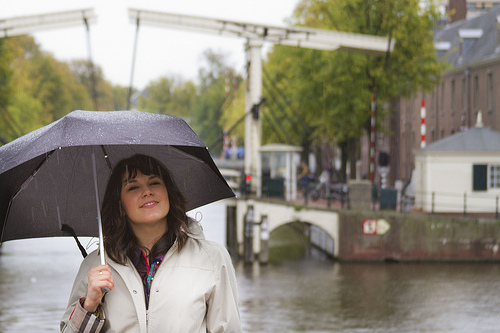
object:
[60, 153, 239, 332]
woman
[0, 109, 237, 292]
umbrella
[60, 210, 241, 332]
jacket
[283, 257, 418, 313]
water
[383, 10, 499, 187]
building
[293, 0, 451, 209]
trees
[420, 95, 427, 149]
pole